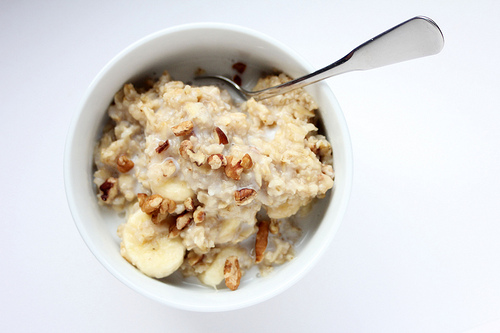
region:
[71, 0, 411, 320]
oatmeal in white bowl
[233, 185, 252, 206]
piece of nut in bowl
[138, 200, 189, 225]
piece of nut in bowl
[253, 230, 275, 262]
piece of nut in bowl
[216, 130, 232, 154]
piece of nut in bowl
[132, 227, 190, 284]
slice of banana in bowl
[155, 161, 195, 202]
slice of banana in bowl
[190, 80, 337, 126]
spoon in the bowl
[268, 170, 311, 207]
clump of creamy oatmeal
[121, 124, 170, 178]
clump of creamy oatmeal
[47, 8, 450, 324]
breakfast, probably, for a food stylist or a photographer trying to sell stock shots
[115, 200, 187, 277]
7/8 a slice of banana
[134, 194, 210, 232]
walnuts &/or pecans chopped atop the rest of the banana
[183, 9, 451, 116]
i believe this is, yes, a spoon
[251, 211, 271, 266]
this, otoh, is a shred, i believe, of pecan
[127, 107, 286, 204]
this is a little milk to make the oats go down easy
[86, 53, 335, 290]
& of course, milk, yr soaking in it. looks like it could be almond milk, actually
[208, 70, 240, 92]
only the smallest of reflections on the edge of the bowl of the spoon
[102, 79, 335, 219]
did i say oatmeal? thats most of it, cooked or, i think, maybe soaked instead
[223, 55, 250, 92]
two little raisiny things that are probably the side of a chop of pecan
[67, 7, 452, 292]
white bowl with food in it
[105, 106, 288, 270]
brown crumbles in bowl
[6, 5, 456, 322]
white bowl on white table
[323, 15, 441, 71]
silver handle of spoon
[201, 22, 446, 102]
spoon sticking out of bowl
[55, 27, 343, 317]
lip of white bowl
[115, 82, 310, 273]
milk in white bowl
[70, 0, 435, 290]
spoon stuck in food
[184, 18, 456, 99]
spoon being used to eat food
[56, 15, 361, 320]
a bowl with oatmeal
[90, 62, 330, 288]
nuts over oatmeal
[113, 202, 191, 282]
a slice of banana in oatmeal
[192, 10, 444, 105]
a spoon inside a bowl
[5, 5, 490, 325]
a bowl on a white surface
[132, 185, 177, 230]
a pecan next a slice of banana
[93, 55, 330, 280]
oatmeal with milk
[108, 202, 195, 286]
a slice of banana over milk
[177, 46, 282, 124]
spoon dipped in the bowl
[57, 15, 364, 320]
bowl is filled with oatmeal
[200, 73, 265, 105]
The spoon inside of the bowl.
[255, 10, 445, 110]
The handle of the spoon.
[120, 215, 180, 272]
The circle slice of banana.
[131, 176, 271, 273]
The walnuts in the oatmeal.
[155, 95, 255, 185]
The crushed walnuts on top of the oatmeal.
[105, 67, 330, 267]
The oatmeal in the bowl.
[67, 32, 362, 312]
The bowl the oatmeal is in.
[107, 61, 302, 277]
The milk inside of the bowl.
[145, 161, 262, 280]
The smaller pieces of banana in the bowl.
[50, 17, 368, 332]
The white table the bowl is set on.